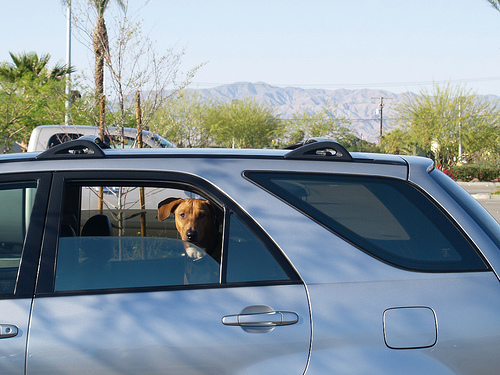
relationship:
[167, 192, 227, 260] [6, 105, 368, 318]
dog in car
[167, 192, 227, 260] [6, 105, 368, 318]
dog i car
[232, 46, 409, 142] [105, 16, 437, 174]
mountain in distance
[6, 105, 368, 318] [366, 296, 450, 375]
car with gas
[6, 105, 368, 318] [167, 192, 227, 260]
car with dog